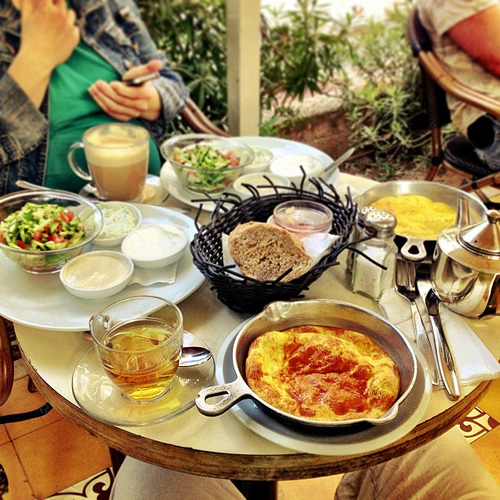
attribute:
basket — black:
[183, 173, 363, 306]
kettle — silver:
[437, 191, 499, 329]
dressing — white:
[130, 224, 188, 264]